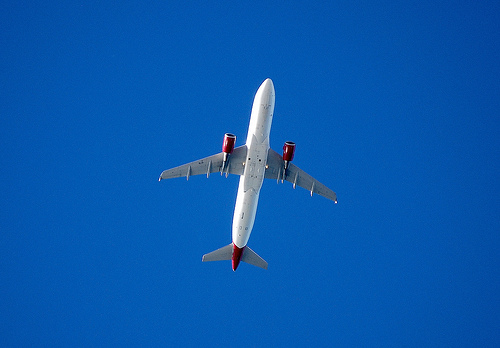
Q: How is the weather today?
A: It is clear.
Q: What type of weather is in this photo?
A: It is clear.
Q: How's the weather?
A: It is clear.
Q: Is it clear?
A: Yes, it is clear.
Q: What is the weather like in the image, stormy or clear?
A: It is clear.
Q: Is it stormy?
A: No, it is clear.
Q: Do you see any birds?
A: No, there are no birds.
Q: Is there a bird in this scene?
A: No, there are no birds.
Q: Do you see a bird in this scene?
A: No, there are no birds.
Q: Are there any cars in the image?
A: No, there are no cars.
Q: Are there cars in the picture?
A: No, there are no cars.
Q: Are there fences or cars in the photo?
A: No, there are no cars or fences.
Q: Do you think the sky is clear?
A: Yes, the sky is clear.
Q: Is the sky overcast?
A: No, the sky is clear.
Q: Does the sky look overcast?
A: No, the sky is clear.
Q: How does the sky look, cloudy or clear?
A: The sky is clear.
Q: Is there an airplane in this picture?
A: Yes, there is an airplane.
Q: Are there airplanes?
A: Yes, there is an airplane.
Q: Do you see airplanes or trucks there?
A: Yes, there is an airplane.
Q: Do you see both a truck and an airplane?
A: No, there is an airplane but no trucks.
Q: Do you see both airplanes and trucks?
A: No, there is an airplane but no trucks.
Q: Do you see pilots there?
A: No, there are no pilots.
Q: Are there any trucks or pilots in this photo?
A: No, there are no pilots or trucks.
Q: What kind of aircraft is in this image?
A: The aircraft is an airplane.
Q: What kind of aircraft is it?
A: The aircraft is an airplane.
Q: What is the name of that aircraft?
A: This is an airplane.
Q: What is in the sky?
A: The plane is in the sky.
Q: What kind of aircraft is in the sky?
A: The aircraft is an airplane.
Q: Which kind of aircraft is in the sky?
A: The aircraft is an airplane.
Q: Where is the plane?
A: The plane is in the sky.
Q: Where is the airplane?
A: The plane is in the sky.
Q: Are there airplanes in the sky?
A: Yes, there is an airplane in the sky.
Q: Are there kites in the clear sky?
A: No, there is an airplane in the sky.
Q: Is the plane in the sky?
A: Yes, the plane is in the sky.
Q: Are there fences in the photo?
A: No, there are no fences.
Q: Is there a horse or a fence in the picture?
A: No, there are no fences or horses.